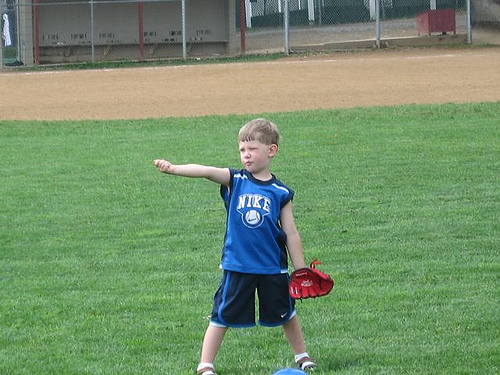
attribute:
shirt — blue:
[218, 162, 293, 274]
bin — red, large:
[414, 6, 459, 38]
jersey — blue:
[217, 172, 284, 269]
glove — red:
[282, 262, 337, 304]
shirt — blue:
[212, 164, 295, 280]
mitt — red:
[286, 264, 335, 301]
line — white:
[6, 48, 457, 73]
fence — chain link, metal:
[3, 2, 498, 76]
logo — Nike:
[235, 193, 272, 228]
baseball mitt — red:
[277, 254, 345, 307]